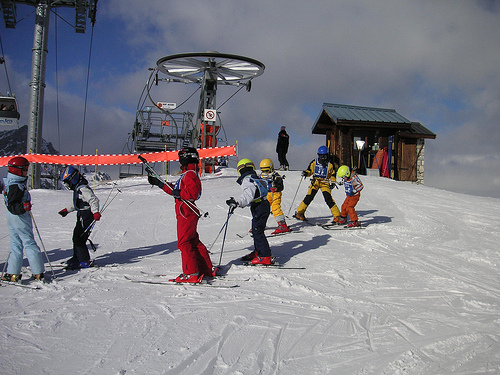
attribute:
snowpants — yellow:
[266, 190, 285, 220]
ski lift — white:
[116, 29, 258, 169]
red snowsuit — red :
[167, 167, 215, 274]